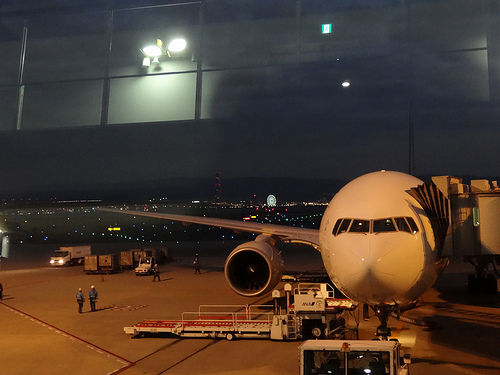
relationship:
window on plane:
[369, 216, 399, 238] [95, 158, 457, 334]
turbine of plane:
[222, 243, 272, 293] [93, 166, 498, 331]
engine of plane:
[216, 244, 274, 298] [138, 188, 431, 334]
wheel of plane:
[374, 327, 395, 347] [90, 168, 440, 339]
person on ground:
[87, 284, 104, 313] [37, 288, 158, 369]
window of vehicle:
[111, 43, 205, 120] [287, 330, 416, 368]